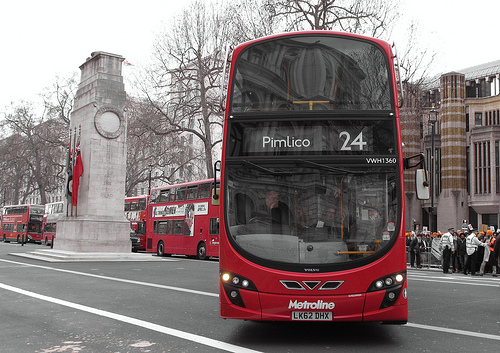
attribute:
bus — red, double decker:
[146, 178, 221, 265]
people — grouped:
[408, 226, 498, 269]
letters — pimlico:
[253, 131, 315, 154]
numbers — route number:
[338, 131, 368, 156]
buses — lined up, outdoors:
[1, 177, 222, 260]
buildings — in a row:
[1, 53, 223, 197]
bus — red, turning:
[220, 35, 414, 321]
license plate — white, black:
[290, 309, 334, 323]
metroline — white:
[287, 298, 337, 312]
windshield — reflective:
[232, 47, 398, 266]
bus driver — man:
[255, 188, 292, 223]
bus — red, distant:
[6, 202, 42, 244]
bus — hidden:
[126, 194, 149, 247]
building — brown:
[405, 65, 500, 259]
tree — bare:
[149, 3, 229, 184]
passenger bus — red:
[41, 201, 66, 247]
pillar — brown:
[438, 74, 473, 245]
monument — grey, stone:
[17, 50, 175, 261]